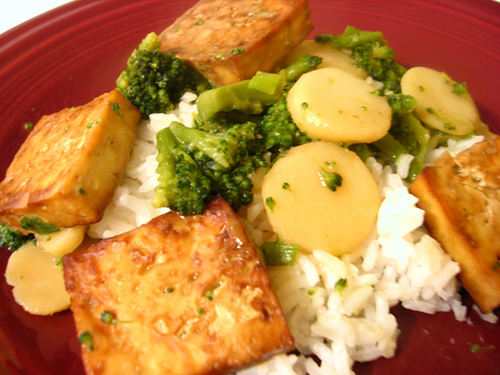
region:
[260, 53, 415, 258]
golden yellow scalloped potatoes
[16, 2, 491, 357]
food on a red plate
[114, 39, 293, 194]
soft cooked broccoli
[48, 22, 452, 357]
food on top of white rice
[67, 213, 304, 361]
square cooked chunks of food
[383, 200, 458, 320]
pure white rice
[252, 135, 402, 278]
potato with broccoli pieces on it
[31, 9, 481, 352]
varied food piled over rice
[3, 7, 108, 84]
grooves on the edge of a plate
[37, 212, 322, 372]
browned square food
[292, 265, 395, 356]
the rice on the plate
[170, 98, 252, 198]
the broccoli on the rice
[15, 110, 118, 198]
the sliced tofu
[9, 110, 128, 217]
the slice of cooked tofu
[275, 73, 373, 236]
the slices of water chestnuts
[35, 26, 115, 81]
the red plate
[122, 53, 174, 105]
the head of broccoli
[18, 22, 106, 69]
the lines on the plate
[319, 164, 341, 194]
small piece of broccoli on the water chestnut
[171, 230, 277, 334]
the browning on the tofu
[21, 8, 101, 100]
The plate is round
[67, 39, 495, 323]
The plate is red in color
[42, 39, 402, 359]
Pieces of tofu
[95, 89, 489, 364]
Rice on the plate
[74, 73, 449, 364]
rice under the tofu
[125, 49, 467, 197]
Broccoli is green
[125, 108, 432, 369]
the rice is under the broccoli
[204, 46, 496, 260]
water chestnuts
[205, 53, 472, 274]
water chestnuts on the rice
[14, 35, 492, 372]
4 squares of tofu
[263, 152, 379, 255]
potato sliced on top of brocolli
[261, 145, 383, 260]
potato with brocolli on top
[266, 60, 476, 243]
a group of potatoes on top of brocolli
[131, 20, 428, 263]
brocolli on top of white rice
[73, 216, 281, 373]
tofu on top of rice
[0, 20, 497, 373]
red plate has food on top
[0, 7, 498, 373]
lots of tofu on top of white rice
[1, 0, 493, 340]
tofu on top of a red plate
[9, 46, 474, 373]
a red plate has tofu, rice, brocolli and potatoes on top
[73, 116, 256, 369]
brocolli and rice and tofu on top of a red plate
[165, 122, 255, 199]
pieces of broccoli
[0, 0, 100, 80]
edge of a red plate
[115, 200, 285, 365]
square cut of tofu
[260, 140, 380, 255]
round water chestnut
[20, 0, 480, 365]
a vegetarian dish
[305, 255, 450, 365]
cooked white rice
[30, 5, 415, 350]
vegetables and tofu on rice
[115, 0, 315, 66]
pieces of tofu and broccoli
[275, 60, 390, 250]
two water chestnuts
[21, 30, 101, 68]
design lines of a red plate